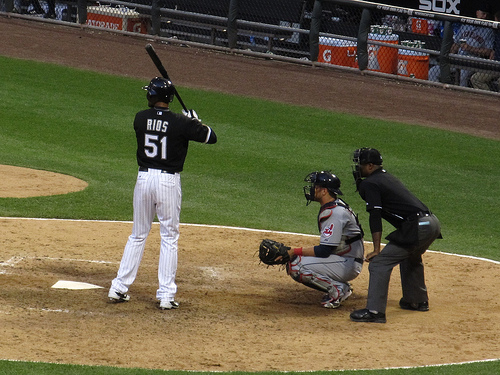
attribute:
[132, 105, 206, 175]
jersey — black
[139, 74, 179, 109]
helmet — black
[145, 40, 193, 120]
bat — black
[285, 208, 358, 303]
uniform — gray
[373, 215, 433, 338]
slacks — gray